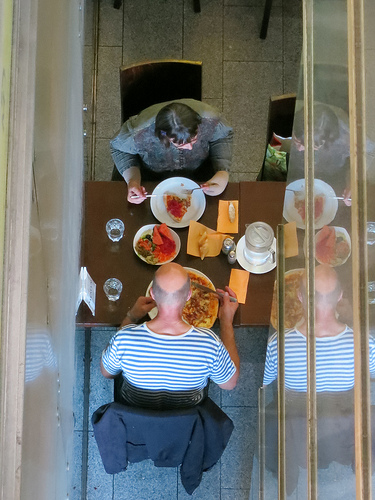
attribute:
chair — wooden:
[110, 58, 203, 178]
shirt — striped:
[109, 324, 255, 409]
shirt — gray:
[110, 97, 235, 180]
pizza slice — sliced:
[158, 187, 195, 226]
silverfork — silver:
[180, 185, 204, 197]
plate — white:
[148, 175, 206, 228]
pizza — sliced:
[162, 190, 189, 222]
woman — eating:
[110, 98, 232, 206]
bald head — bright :
[153, 258, 191, 296]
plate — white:
[155, 181, 212, 220]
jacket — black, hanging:
[88, 395, 235, 494]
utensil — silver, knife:
[126, 184, 174, 205]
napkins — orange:
[194, 213, 286, 315]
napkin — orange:
[226, 266, 251, 304]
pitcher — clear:
[241, 220, 275, 265]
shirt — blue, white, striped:
[95, 314, 242, 390]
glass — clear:
[104, 217, 124, 242]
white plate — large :
[149, 176, 208, 230]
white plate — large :
[235, 231, 277, 272]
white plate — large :
[131, 224, 180, 263]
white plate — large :
[144, 264, 219, 329]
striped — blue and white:
[112, 323, 231, 396]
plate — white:
[141, 266, 217, 329]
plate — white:
[134, 222, 180, 264]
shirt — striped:
[99, 313, 238, 413]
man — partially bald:
[92, 262, 244, 417]